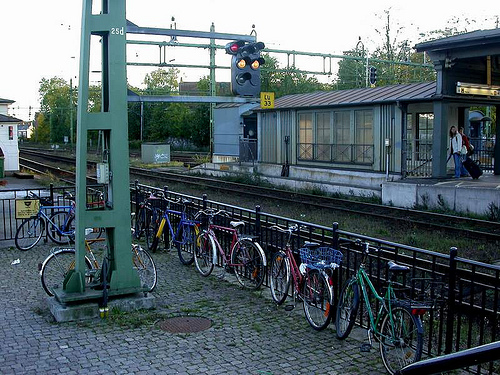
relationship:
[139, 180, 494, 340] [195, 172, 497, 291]
railing next to tracks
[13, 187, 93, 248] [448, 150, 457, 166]
bike in ground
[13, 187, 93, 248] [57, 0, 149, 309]
bike behind metal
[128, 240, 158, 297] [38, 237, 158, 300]
tire of bike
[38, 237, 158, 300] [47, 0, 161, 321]
bike behind structure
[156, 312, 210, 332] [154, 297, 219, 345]
cover over manhole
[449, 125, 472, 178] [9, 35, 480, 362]
person waiting at trainstation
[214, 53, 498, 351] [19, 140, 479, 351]
house next to tracks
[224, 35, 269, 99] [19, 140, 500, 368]
signal light above tracks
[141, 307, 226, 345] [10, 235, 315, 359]
manhole on platform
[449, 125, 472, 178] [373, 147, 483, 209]
person waiting on platform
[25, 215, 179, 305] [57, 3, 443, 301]
bike against structure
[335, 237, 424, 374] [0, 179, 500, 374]
greenbike linked to fence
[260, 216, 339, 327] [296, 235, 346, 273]
bike with basket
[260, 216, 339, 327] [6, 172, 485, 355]
bike against fence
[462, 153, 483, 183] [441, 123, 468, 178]
luggage belonging to woman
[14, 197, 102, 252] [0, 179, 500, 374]
bike on far side of fence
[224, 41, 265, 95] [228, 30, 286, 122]
signal light for trains